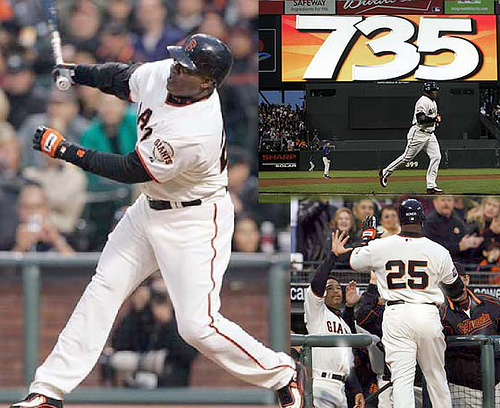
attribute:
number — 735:
[283, 14, 497, 80]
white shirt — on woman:
[304, 289, 356, 384]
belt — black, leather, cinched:
[140, 187, 222, 210]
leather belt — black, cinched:
[140, 190, 207, 215]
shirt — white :
[127, 56, 227, 195]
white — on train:
[399, 243, 420, 255]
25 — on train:
[372, 253, 433, 293]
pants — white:
[27, 188, 297, 395]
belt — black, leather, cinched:
[381, 288, 446, 318]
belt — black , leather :
[410, 117, 434, 135]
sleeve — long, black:
[62, 138, 153, 185]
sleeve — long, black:
[76, 58, 141, 98]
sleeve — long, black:
[310, 251, 337, 296]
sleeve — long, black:
[415, 110, 436, 125]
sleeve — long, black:
[437, 275, 465, 299]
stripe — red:
[204, 197, 262, 369]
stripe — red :
[205, 201, 295, 371]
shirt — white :
[131, 59, 235, 203]